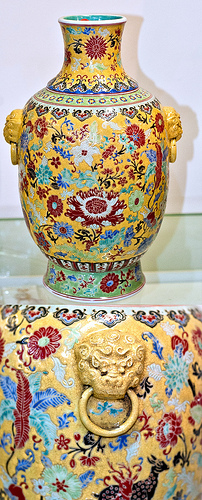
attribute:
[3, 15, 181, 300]
vase — here, yellow, antique, big, sitting, large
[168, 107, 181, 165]
yellow emblem — intricate, animals head, head, handle, affixed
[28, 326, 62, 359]
flower — red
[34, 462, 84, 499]
flower — green, turquoise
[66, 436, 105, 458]
vine — black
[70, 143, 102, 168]
flower — white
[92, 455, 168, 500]
deer — black, painted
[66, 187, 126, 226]
red and white flower — large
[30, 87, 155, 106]
pattern — colorful